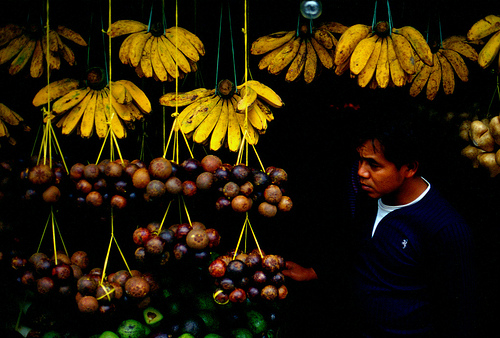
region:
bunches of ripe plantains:
[3, 18, 492, 147]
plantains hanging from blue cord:
[334, 2, 434, 83]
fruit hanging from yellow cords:
[12, 162, 293, 312]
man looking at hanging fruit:
[346, 123, 467, 332]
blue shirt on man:
[356, 181, 478, 335]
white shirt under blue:
[363, 179, 430, 240]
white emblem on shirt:
[400, 235, 410, 250]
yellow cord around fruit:
[97, 282, 115, 304]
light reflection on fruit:
[185, 160, 197, 172]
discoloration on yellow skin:
[183, 103, 213, 129]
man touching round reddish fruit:
[346, 125, 491, 335]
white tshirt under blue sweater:
[366, 175, 426, 235]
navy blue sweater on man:
[345, 170, 465, 330]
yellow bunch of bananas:
[330, 21, 432, 86]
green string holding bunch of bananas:
[370, 0, 392, 35]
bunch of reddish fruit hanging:
[195, 150, 290, 215]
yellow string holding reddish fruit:
[230, 0, 265, 170]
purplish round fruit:
[225, 255, 241, 275]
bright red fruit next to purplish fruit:
[205, 255, 225, 275]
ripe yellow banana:
[347, 33, 377, 71]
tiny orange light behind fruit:
[316, 94, 373, 116]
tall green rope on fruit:
[216, 19, 238, 66]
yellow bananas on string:
[169, 72, 292, 142]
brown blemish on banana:
[182, 110, 211, 122]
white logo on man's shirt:
[394, 232, 411, 257]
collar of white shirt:
[368, 194, 418, 216]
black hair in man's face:
[356, 134, 384, 154]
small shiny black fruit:
[222, 255, 249, 275]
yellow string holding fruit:
[97, 223, 137, 270]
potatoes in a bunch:
[448, 106, 488, 163]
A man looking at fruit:
[2, 5, 467, 337]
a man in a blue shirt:
[325, 113, 472, 336]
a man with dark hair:
[327, 110, 469, 337]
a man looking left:
[338, 117, 469, 337]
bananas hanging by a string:
[108, 4, 207, 85]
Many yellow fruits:
[101, 13, 208, 85]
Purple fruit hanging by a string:
[200, 128, 291, 228]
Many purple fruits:
[210, 249, 290, 304]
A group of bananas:
[249, 12, 499, 104]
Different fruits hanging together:
[20, 75, 292, 220]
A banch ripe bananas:
[350, 5, 405, 72]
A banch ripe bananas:
[420, 36, 483, 96]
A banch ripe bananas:
[251, 21, 328, 72]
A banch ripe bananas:
[179, 82, 286, 152]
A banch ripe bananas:
[104, 12, 201, 74]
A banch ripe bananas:
[36, 81, 141, 145]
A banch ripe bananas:
[8, 18, 80, 70]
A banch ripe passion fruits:
[225, 234, 282, 305]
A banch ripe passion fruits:
[130, 210, 221, 268]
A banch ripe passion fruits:
[11, 233, 146, 307]